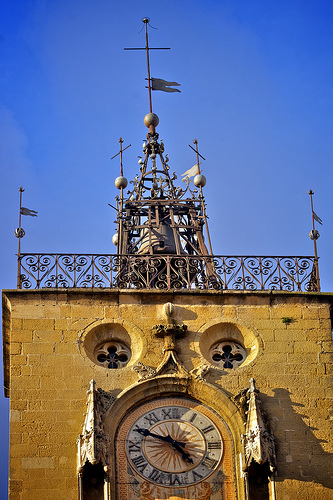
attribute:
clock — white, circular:
[98, 360, 285, 483]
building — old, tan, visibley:
[28, 61, 326, 495]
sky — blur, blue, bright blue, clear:
[19, 35, 120, 119]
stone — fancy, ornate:
[30, 316, 75, 390]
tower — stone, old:
[72, 86, 229, 287]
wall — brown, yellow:
[246, 323, 323, 430]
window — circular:
[71, 304, 177, 367]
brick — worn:
[61, 313, 306, 380]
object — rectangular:
[232, 374, 275, 473]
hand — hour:
[167, 435, 199, 467]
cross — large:
[116, 14, 180, 79]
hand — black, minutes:
[133, 425, 187, 448]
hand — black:
[163, 431, 193, 462]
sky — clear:
[0, 0, 331, 500]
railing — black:
[14, 247, 320, 293]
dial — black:
[133, 425, 188, 444]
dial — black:
[164, 431, 194, 461]